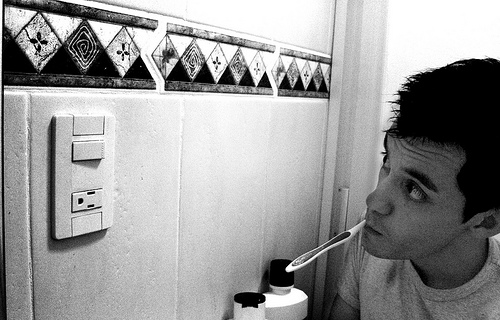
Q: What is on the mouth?
A: Toothbrush.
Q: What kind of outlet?
A: Electrical.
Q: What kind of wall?
A: Tiled.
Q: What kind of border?
A: Tile.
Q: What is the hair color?
A: Dark.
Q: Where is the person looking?
A: Wall.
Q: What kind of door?
A: Folding.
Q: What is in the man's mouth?
A: A toothbrush.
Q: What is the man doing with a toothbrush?
A: Brushing teeth.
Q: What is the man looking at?
A: A wall socket.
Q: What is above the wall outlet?
A: Tile pattern.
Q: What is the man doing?
A: Brushing his teeth.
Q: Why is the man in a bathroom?
A: To brush teeth.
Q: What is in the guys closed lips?
A: A toothbrush.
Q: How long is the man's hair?
A: Short.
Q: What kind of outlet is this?
A: An electrical one.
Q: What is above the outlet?
A: Some tiles.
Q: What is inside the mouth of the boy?
A: Tooth brush.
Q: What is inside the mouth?
A: Head of toothbrush.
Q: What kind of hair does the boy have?
A: Dark hair.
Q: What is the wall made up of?
A: Tiles.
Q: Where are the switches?
A: On the wall.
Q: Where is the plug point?
A: On the wall.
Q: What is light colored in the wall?
A: Electrical outlet.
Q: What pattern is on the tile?
A: Diamond pattern.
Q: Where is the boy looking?
A: Electrical outlet.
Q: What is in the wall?
A: Tile.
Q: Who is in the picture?
A: A boy.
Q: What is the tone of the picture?
A: Black and white.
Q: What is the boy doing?
A: Brushing teeth.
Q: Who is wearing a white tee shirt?
A: The boy.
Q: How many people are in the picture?
A: One.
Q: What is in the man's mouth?
A: Toothbrush.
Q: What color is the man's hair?
A: Black.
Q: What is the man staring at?
A: The wall.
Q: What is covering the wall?
A: Tiles.